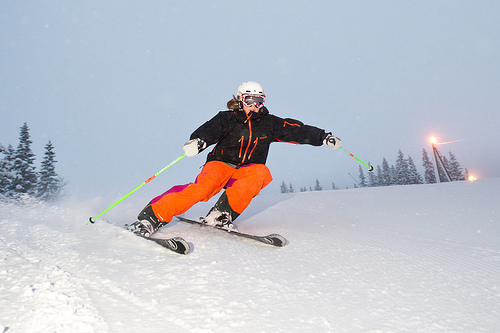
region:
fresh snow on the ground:
[335, 218, 442, 297]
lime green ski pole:
[81, 153, 198, 228]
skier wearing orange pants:
[166, 149, 276, 219]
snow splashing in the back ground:
[33, 168, 96, 218]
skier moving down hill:
[127, 71, 312, 266]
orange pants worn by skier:
[160, 153, 260, 230]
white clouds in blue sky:
[44, 19, 129, 93]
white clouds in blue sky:
[102, 91, 116, 109]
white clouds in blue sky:
[419, 27, 450, 46]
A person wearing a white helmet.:
[225, 81, 275, 117]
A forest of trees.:
[1, 121, 67, 205]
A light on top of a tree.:
[426, 132, 440, 147]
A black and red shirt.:
[190, 108, 327, 167]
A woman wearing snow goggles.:
[240, 95, 267, 120]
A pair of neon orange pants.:
[148, 162, 275, 226]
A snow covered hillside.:
[0, 175, 497, 330]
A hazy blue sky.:
[0, 0, 498, 197]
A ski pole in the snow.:
[87, 137, 208, 231]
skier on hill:
[110, 79, 321, 271]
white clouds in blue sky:
[62, 38, 87, 57]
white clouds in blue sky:
[335, 50, 359, 81]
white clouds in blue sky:
[59, 46, 115, 85]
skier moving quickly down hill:
[115, 68, 327, 275]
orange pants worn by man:
[179, 165, 273, 216]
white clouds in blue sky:
[19, 11, 66, 49]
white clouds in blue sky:
[79, 105, 123, 136]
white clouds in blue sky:
[116, 52, 156, 86]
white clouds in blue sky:
[327, 13, 372, 65]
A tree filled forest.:
[0, 122, 71, 214]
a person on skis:
[103, 48, 380, 281]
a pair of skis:
[70, 177, 299, 269]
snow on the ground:
[19, 172, 496, 324]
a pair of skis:
[89, 205, 289, 259]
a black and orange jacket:
[173, 86, 316, 172]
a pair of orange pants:
[126, 157, 270, 235]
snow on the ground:
[17, 157, 497, 327]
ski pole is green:
[91, 144, 205, 227]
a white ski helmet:
[224, 72, 270, 104]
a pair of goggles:
[236, 85, 275, 122]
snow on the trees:
[10, 121, 65, 196]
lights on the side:
[419, 122, 476, 190]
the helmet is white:
[234, 81, 264, 96]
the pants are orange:
[148, 162, 273, 222]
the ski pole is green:
[84, 152, 188, 224]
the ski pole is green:
[329, 137, 374, 174]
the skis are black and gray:
[101, 212, 287, 254]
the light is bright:
[427, 134, 437, 145]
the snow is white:
[0, 175, 499, 330]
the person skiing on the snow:
[0, 81, 499, 331]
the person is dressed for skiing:
[85, 80, 375, 254]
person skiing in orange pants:
[123, 80, 341, 237]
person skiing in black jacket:
[124, 80, 341, 239]